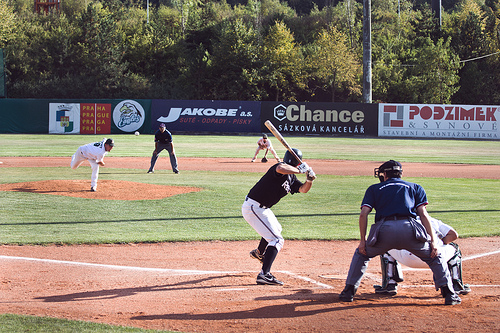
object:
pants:
[240, 198, 285, 257]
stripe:
[248, 204, 280, 248]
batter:
[238, 146, 315, 287]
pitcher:
[70, 137, 115, 193]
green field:
[0, 134, 499, 165]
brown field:
[0, 235, 499, 332]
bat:
[262, 119, 306, 168]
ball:
[132, 130, 144, 137]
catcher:
[370, 214, 471, 297]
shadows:
[31, 272, 258, 305]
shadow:
[127, 298, 451, 321]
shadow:
[250, 287, 447, 302]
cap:
[103, 138, 116, 147]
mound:
[0, 177, 204, 202]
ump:
[336, 160, 458, 307]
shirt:
[359, 177, 429, 220]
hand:
[294, 162, 310, 174]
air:
[10, 113, 35, 130]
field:
[0, 131, 499, 332]